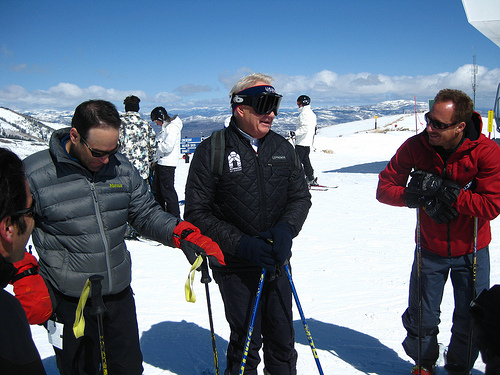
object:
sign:
[180, 136, 201, 154]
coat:
[183, 116, 312, 270]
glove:
[172, 221, 226, 271]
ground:
[328, 176, 342, 199]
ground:
[342, 115, 384, 159]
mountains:
[0, 100, 430, 161]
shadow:
[294, 318, 419, 375]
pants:
[46, 290, 144, 375]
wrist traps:
[185, 253, 203, 303]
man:
[0, 73, 500, 375]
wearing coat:
[183, 116, 312, 272]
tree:
[472, 54, 479, 111]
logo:
[227, 151, 242, 173]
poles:
[78, 276, 152, 373]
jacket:
[22, 127, 183, 297]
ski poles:
[240, 267, 267, 374]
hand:
[238, 235, 275, 272]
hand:
[259, 222, 297, 266]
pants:
[194, 240, 307, 373]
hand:
[9, 252, 57, 325]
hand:
[172, 221, 226, 271]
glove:
[9, 252, 53, 326]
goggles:
[231, 92, 284, 116]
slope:
[0, 110, 482, 369]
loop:
[72, 279, 90, 340]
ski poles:
[467, 217, 477, 375]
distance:
[5, 6, 495, 153]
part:
[211, 137, 301, 264]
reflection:
[139, 318, 484, 374]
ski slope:
[0, 108, 495, 375]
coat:
[376, 111, 498, 257]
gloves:
[405, 170, 461, 224]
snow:
[314, 223, 399, 315]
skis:
[308, 185, 339, 191]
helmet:
[297, 95, 311, 106]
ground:
[7, 183, 485, 340]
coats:
[157, 115, 183, 167]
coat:
[293, 105, 317, 146]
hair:
[228, 72, 274, 98]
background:
[0, 0, 500, 262]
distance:
[3, 10, 495, 119]